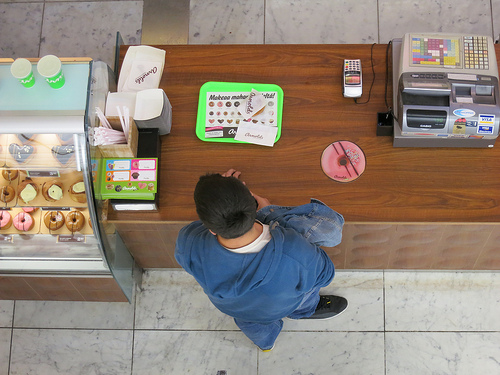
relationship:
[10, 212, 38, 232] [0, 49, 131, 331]
donut on display case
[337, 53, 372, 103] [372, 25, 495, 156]
card reader next to register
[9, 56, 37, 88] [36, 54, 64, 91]
cup next to cup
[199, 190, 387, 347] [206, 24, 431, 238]
man at counter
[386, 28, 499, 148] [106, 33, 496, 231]
cash register on counter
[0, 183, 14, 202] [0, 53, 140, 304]
donut on counter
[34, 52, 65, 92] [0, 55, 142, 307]
cup on case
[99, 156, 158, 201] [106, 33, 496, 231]
box on counter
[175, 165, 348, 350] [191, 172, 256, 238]
man as head full hair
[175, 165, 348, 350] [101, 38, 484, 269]
man standing at checkout counter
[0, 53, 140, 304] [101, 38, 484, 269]
counter next to checkout counter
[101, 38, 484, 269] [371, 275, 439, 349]
checkout counter on floor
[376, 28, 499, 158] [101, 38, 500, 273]
cash register on checkout counter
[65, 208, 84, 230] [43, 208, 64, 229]
donut next to donut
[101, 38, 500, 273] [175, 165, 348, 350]
checkout counter in front of man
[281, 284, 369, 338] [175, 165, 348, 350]
black shoes on man